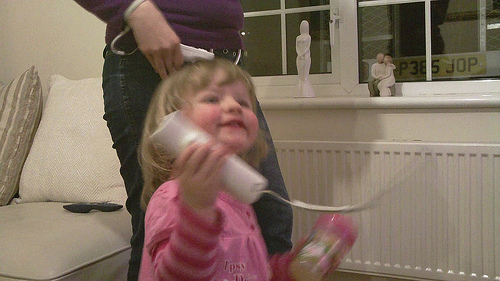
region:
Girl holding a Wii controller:
[138, 55, 356, 280]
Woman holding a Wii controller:
[72, 1, 294, 278]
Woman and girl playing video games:
[75, 0, 360, 279]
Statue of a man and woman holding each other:
[365, 50, 399, 96]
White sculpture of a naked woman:
[292, 17, 313, 100]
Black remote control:
[60, 198, 122, 215]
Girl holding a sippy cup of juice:
[137, 56, 358, 279]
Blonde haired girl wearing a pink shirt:
[132, 56, 354, 279]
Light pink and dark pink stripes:
[145, 198, 224, 279]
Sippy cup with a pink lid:
[290, 208, 358, 279]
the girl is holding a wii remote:
[147, 103, 389, 278]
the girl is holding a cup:
[286, 173, 325, 272]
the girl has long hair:
[142, 80, 241, 187]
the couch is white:
[38, 79, 128, 278]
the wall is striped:
[316, 122, 447, 247]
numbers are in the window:
[356, 57, 491, 138]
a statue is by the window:
[271, 15, 316, 66]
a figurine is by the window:
[351, 43, 456, 125]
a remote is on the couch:
[50, 181, 135, 216]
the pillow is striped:
[2, 78, 89, 231]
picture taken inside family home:
[0, 0, 498, 279]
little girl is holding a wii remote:
[153, 110, 434, 216]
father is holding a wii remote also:
[110, 22, 216, 75]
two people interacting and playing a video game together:
[69, 0, 358, 280]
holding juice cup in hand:
[289, 214, 358, 279]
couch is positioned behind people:
[0, 69, 137, 279]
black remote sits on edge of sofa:
[62, 200, 124, 216]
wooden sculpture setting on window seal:
[367, 52, 395, 96]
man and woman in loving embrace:
[366, 53, 398, 98]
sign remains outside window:
[359, 45, 497, 78]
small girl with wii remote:
[130, 53, 275, 278]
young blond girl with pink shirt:
[130, 55, 280, 280]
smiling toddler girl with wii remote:
[130, 50, 300, 280]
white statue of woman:
[285, 10, 320, 100]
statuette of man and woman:
[360, 50, 400, 97]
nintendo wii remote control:
[145, 107, 270, 210]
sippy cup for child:
[288, 196, 361, 278]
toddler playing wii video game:
[128, 53, 292, 280]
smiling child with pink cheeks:
[136, 54, 273, 183]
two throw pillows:
[1, 69, 129, 202]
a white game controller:
[153, 115, 270, 205]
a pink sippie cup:
[286, 207, 356, 278]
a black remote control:
[61, 197, 121, 215]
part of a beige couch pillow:
[12, 67, 125, 202]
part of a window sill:
[252, 97, 496, 111]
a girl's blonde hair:
[132, 55, 276, 205]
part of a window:
[343, 0, 498, 85]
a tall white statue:
[294, 17, 317, 99]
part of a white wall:
[0, 5, 100, 72]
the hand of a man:
[127, 5, 187, 75]